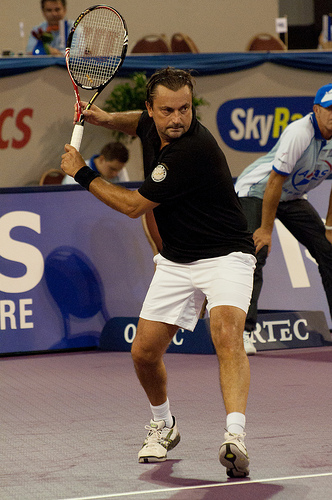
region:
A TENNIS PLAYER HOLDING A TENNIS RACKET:
[56, 1, 258, 480]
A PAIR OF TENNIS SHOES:
[130, 414, 257, 484]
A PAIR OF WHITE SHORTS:
[134, 249, 257, 334]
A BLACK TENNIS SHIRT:
[133, 105, 260, 269]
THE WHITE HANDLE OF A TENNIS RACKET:
[65, 122, 88, 176]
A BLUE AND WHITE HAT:
[304, 83, 331, 113]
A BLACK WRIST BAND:
[71, 162, 102, 191]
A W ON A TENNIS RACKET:
[76, 21, 121, 67]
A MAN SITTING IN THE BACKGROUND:
[18, 1, 89, 60]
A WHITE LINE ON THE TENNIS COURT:
[105, 469, 329, 497]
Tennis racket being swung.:
[57, 2, 135, 182]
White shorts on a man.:
[129, 249, 258, 338]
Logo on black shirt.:
[136, 161, 177, 190]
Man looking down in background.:
[65, 140, 141, 193]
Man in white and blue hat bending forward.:
[226, 78, 329, 375]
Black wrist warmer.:
[72, 153, 104, 191]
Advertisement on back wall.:
[215, 86, 331, 180]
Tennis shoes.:
[129, 405, 277, 484]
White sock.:
[140, 394, 176, 429]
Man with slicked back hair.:
[134, 63, 212, 147]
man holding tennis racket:
[56, 0, 259, 481]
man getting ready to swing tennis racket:
[54, 3, 263, 485]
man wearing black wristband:
[53, 2, 264, 484]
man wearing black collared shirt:
[54, 0, 257, 487]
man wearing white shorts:
[54, 3, 256, 498]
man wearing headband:
[49, 1, 270, 494]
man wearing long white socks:
[59, 2, 261, 487]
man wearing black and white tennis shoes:
[50, 4, 261, 481]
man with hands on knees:
[222, 71, 329, 368]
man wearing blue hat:
[226, 81, 328, 360]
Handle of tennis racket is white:
[69, 122, 81, 161]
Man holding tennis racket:
[58, 65, 260, 475]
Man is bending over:
[231, 77, 331, 362]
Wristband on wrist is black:
[68, 162, 100, 189]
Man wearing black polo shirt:
[68, 66, 254, 479]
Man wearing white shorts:
[62, 68, 255, 479]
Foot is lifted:
[216, 414, 250, 481]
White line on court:
[63, 468, 330, 498]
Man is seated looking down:
[63, 136, 131, 184]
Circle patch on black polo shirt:
[147, 160, 167, 184]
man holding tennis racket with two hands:
[52, 63, 132, 217]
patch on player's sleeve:
[148, 155, 186, 195]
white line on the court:
[122, 464, 312, 498]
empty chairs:
[132, 16, 310, 53]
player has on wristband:
[30, 151, 109, 203]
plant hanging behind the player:
[94, 46, 253, 156]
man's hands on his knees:
[251, 135, 329, 260]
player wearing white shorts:
[140, 250, 301, 383]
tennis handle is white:
[67, 113, 89, 169]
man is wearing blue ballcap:
[308, 86, 329, 111]